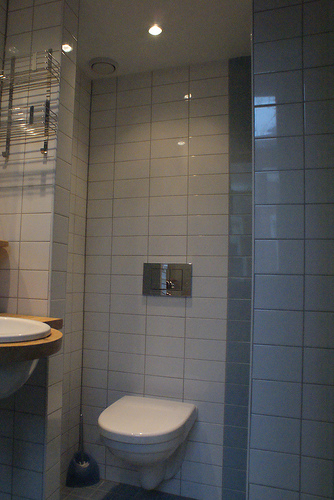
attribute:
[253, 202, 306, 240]
tile — white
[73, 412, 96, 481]
brush — toilet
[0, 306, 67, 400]
counter — brown 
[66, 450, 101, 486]
holder — blue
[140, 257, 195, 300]
window — collection, metal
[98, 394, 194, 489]
toilet bowl — ceramic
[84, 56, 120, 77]
detector — smoke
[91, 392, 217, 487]
toilet bowl — white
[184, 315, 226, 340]
tile — white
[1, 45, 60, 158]
rack — metal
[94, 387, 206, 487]
toilet — white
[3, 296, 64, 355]
counter — tan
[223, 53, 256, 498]
tile — blue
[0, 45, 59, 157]
shelf — metal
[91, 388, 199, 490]
toilet — clean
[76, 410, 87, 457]
handle — blue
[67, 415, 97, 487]
cleaner — toilet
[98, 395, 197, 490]
toilet — porcelain